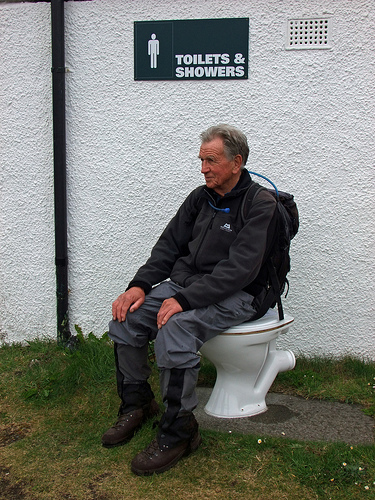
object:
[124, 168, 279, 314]
jacket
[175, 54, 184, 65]
letter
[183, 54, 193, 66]
letter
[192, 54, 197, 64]
letter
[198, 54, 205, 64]
letter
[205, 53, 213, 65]
letter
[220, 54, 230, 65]
letter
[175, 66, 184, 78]
letter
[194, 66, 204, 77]
letter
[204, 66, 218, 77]
letter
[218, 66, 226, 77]
letter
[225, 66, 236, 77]
letter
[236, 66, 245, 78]
letter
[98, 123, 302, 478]
man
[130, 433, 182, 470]
leather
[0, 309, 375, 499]
green grass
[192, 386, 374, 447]
concrete pad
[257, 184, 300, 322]
backpack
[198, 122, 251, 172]
graying hair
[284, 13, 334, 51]
vent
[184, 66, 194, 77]
letter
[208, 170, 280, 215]
microphone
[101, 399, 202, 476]
boots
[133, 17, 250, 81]
sign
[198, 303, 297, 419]
toilet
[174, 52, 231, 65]
toilet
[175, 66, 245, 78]
shower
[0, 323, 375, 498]
lawn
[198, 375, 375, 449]
spot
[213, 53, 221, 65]
letter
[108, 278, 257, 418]
pants